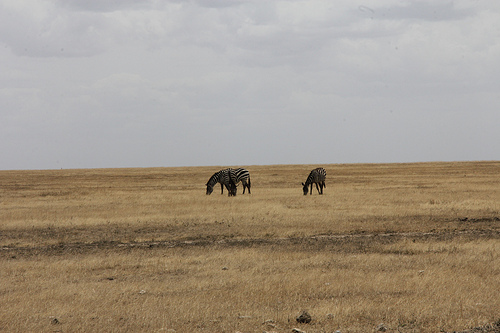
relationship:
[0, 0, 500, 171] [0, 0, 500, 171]
cloud in sky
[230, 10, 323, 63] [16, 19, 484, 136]
cloud in sky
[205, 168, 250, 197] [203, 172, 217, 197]
zebra has head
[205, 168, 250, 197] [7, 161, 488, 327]
zebra standing in field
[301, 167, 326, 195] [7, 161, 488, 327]
zebra standing in field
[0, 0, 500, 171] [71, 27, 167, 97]
cloud in sky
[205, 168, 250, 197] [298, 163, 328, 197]
zebra grazing of zebra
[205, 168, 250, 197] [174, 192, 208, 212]
zebra grazing of grass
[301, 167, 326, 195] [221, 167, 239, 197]
zebra in zebra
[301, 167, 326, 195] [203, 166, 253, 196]
zebra in zebra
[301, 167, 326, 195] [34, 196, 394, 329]
zebra in barron landscape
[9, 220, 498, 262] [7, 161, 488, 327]
dirt in field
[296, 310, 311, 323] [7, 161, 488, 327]
rock in field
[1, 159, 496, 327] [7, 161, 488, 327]
grass in field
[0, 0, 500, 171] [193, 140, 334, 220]
sky above zebras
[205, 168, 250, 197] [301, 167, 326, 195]
zebra in zebra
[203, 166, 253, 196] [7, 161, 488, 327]
zebra in field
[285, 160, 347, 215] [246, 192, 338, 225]
zebra eating grass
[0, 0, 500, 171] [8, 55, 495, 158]
cloud in sky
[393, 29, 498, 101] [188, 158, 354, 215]
sky behind zebras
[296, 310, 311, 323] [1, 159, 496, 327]
rock in grass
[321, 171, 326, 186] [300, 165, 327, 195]
tail of zebra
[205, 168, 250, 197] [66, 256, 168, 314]
zebra feeding on grass